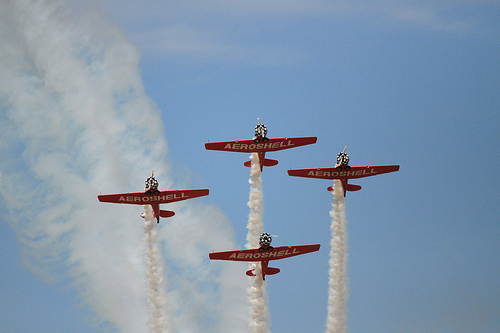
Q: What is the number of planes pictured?
A: 4.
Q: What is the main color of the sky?
A: Blue.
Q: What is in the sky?
A: Cloud.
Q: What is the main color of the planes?
A: Red.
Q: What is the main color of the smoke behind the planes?
A: White.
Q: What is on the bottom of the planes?
A: Aeroshell.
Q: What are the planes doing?
A: Flying.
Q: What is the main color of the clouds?
A: White.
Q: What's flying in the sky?
A: Planes.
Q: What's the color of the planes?
A: Red.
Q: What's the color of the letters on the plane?
A: White.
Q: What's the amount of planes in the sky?
A: Four.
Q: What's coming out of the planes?
A: Smoke.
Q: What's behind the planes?
A: Smoke trails.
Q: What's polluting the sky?
A: Smoke trails.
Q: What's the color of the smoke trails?
A: White.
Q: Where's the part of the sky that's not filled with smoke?
A: Right side.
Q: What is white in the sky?
A: Smoke.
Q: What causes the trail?
A: Vapor.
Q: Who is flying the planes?
A: Pilots.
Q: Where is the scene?
A: In the sky.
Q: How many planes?
A: 4.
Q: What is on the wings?
A: AEROSHELL.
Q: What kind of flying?
A: Precision flying.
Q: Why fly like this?
A: Air show.